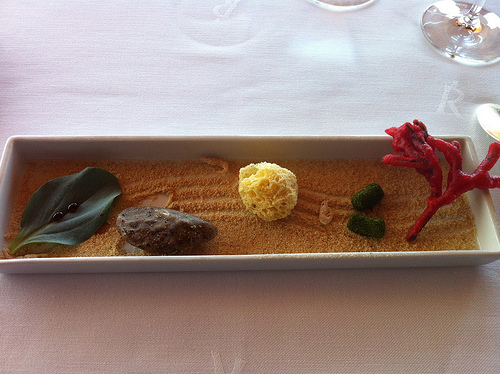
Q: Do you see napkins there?
A: No, there are no napkins.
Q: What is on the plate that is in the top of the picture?
A: The sugar is on the plate.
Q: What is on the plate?
A: The sugar is on the plate.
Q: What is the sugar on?
A: The sugar is on the plate.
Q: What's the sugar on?
A: The sugar is on the plate.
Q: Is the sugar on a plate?
A: Yes, the sugar is on a plate.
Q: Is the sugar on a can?
A: No, the sugar is on a plate.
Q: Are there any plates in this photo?
A: Yes, there is a plate.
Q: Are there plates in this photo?
A: Yes, there is a plate.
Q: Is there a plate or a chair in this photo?
A: Yes, there is a plate.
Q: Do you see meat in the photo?
A: No, there is no meat.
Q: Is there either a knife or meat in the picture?
A: No, there are no meat or knives.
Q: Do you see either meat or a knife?
A: No, there are no meat or knives.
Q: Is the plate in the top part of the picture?
A: Yes, the plate is in the top of the image.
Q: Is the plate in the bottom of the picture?
A: No, the plate is in the top of the image.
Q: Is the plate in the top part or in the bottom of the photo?
A: The plate is in the top of the image.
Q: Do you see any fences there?
A: No, there are no fences.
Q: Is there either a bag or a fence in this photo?
A: No, there are no fences or bags.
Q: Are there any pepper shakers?
A: No, there are no pepper shakers.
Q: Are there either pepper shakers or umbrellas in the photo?
A: No, there are no pepper shakers or umbrellas.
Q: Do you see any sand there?
A: Yes, there is sand.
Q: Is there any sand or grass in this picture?
A: Yes, there is sand.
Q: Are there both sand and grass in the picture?
A: No, there is sand but no grass.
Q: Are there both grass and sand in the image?
A: No, there is sand but no grass.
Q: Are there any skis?
A: No, there are no skis.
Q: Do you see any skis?
A: No, there are no skis.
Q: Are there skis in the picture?
A: No, there are no skis.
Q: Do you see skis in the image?
A: No, there are no skis.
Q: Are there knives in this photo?
A: No, there are no knives.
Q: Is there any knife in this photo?
A: No, there are no knives.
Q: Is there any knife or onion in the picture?
A: No, there are no knives or onions.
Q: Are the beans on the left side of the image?
A: Yes, the beans are on the left of the image.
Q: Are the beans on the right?
A: No, the beans are on the left of the image.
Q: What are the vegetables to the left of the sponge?
A: The vegetables are beans.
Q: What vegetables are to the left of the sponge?
A: The vegetables are beans.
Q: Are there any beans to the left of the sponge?
A: Yes, there are beans to the left of the sponge.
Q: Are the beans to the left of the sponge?
A: Yes, the beans are to the left of the sponge.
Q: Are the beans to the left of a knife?
A: No, the beans are to the left of the sponge.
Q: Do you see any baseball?
A: No, there are no baseballs.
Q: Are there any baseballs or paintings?
A: No, there are no baseballs or paintings.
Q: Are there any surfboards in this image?
A: No, there are no surfboards.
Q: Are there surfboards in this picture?
A: No, there are no surfboards.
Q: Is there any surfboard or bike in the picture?
A: No, there are no surfboards or bikes.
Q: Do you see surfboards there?
A: No, there are no surfboards.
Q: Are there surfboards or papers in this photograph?
A: No, there are no surfboards or papers.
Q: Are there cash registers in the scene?
A: No, there are no cash registers.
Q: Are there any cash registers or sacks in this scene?
A: No, there are no cash registers or sacks.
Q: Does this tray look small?
A: Yes, the tray is small.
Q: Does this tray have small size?
A: Yes, the tray is small.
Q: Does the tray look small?
A: Yes, the tray is small.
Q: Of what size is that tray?
A: The tray is small.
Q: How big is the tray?
A: The tray is small.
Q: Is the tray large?
A: No, the tray is small.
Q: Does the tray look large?
A: No, the tray is small.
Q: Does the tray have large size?
A: No, the tray is small.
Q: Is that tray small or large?
A: The tray is small.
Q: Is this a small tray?
A: Yes, this is a small tray.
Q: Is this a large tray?
A: No, this is a small tray.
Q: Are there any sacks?
A: No, there are no sacks.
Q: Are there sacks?
A: No, there are no sacks.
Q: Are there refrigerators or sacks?
A: No, there are no sacks or refrigerators.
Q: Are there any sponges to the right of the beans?
A: Yes, there is a sponge to the right of the beans.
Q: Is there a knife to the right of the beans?
A: No, there is a sponge to the right of the beans.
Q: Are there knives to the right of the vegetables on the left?
A: No, there is a sponge to the right of the beans.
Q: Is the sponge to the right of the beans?
A: Yes, the sponge is to the right of the beans.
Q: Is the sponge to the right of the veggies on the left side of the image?
A: Yes, the sponge is to the right of the beans.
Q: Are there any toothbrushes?
A: No, there are no toothbrushes.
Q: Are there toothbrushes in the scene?
A: No, there are no toothbrushes.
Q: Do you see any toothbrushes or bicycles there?
A: No, there are no toothbrushes or bicycles.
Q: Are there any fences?
A: No, there are no fences.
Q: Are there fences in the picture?
A: No, there are no fences.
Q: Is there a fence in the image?
A: No, there are no fences.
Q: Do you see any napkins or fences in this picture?
A: No, there are no fences or napkins.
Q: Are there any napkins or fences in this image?
A: No, there are no fences or napkins.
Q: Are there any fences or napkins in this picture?
A: No, there are no fences or napkins.